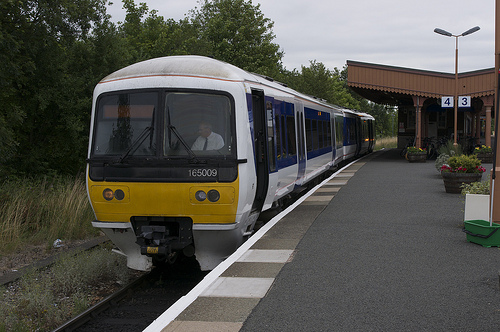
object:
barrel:
[441, 172, 481, 194]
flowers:
[440, 154, 486, 173]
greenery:
[448, 155, 478, 164]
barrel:
[406, 151, 427, 162]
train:
[80, 52, 376, 275]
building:
[340, 53, 500, 162]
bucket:
[462, 218, 498, 247]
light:
[431, 22, 483, 154]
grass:
[0, 178, 90, 249]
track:
[48, 266, 200, 332]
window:
[273, 97, 294, 168]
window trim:
[304, 105, 332, 163]